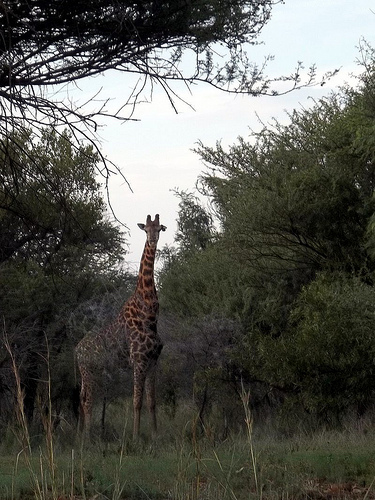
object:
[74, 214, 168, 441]
giraffe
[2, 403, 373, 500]
field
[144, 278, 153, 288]
spot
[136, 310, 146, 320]
spot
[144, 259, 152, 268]
spot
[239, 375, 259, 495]
plant blade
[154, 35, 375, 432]
tree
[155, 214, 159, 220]
ossicone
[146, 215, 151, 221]
ossicone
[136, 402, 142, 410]
knee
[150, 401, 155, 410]
knee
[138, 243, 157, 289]
neck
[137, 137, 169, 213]
cloud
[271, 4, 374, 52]
sky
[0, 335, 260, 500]
grass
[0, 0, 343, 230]
branch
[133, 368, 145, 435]
leg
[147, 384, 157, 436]
leg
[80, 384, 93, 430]
leg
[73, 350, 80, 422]
tail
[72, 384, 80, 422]
hair